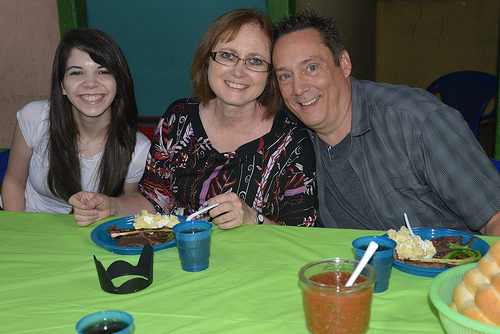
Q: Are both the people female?
A: No, they are both male and female.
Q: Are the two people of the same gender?
A: No, they are both male and female.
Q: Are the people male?
A: No, they are both male and female.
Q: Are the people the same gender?
A: No, they are both male and female.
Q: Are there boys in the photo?
A: No, there are no boys.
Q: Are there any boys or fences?
A: No, there are no boys or fences.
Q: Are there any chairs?
A: Yes, there is a chair.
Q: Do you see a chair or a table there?
A: Yes, there is a chair.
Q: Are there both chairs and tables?
A: Yes, there are both a chair and a table.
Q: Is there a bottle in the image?
A: No, there are no bottles.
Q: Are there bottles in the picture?
A: No, there are no bottles.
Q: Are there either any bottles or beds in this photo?
A: No, there are no bottles or beds.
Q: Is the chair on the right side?
A: Yes, the chair is on the right of the image.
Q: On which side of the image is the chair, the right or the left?
A: The chair is on the right of the image.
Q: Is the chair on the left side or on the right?
A: The chair is on the right of the image.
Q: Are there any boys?
A: No, there are no boys.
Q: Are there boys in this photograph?
A: No, there are no boys.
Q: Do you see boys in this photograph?
A: No, there are no boys.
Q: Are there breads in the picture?
A: Yes, there is a bread.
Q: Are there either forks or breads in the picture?
A: Yes, there is a bread.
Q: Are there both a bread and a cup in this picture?
A: Yes, there are both a bread and a cup.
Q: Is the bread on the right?
A: Yes, the bread is on the right of the image.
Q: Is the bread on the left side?
A: No, the bread is on the right of the image.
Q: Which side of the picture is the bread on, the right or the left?
A: The bread is on the right of the image.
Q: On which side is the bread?
A: The bread is on the right of the image.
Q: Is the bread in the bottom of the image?
A: Yes, the bread is in the bottom of the image.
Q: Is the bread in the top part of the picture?
A: No, the bread is in the bottom of the image.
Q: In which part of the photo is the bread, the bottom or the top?
A: The bread is in the bottom of the image.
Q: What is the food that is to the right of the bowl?
A: The food is a bread.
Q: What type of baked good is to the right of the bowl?
A: The food is a bread.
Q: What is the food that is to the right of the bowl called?
A: The food is a bread.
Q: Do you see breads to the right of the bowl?
A: Yes, there is a bread to the right of the bowl.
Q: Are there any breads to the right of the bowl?
A: Yes, there is a bread to the right of the bowl.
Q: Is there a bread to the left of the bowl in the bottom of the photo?
A: No, the bread is to the right of the bowl.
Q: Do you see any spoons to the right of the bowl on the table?
A: No, there is a bread to the right of the bowl.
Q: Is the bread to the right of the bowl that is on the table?
A: Yes, the bread is to the right of the bowl.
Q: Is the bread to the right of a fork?
A: No, the bread is to the right of the bowl.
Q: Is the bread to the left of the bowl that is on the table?
A: No, the bread is to the right of the bowl.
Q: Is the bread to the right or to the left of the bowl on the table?
A: The bread is to the right of the bowl.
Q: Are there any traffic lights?
A: No, there are no traffic lights.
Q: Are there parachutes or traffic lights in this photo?
A: No, there are no traffic lights or parachutes.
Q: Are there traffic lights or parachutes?
A: No, there are no traffic lights or parachutes.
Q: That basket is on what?
A: The basket is on the table.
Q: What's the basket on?
A: The basket is on the table.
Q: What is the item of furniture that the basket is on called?
A: The piece of furniture is a table.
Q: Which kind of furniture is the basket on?
A: The basket is on the table.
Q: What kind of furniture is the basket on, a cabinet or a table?
A: The basket is on a table.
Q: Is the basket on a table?
A: Yes, the basket is on a table.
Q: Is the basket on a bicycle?
A: No, the basket is on a table.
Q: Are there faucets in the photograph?
A: No, there are no faucets.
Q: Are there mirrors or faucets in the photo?
A: No, there are no faucets or mirrors.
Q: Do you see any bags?
A: No, there are no bags.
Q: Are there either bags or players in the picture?
A: No, there are no bags or players.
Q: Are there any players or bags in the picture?
A: No, there are no bags or players.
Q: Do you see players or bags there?
A: No, there are no bags or players.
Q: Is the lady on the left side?
A: Yes, the lady is on the left of the image.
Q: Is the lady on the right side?
A: No, the lady is on the left of the image.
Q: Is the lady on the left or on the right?
A: The lady is on the left of the image.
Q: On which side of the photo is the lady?
A: The lady is on the left of the image.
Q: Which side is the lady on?
A: The lady is on the left of the image.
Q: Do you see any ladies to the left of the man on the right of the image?
A: Yes, there is a lady to the left of the man.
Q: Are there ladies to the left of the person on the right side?
A: Yes, there is a lady to the left of the man.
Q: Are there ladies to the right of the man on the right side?
A: No, the lady is to the left of the man.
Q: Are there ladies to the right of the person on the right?
A: No, the lady is to the left of the man.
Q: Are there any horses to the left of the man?
A: No, there is a lady to the left of the man.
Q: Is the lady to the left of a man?
A: Yes, the lady is to the left of a man.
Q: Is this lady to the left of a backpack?
A: No, the lady is to the left of a man.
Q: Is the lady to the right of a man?
A: No, the lady is to the left of a man.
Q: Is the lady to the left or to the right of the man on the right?
A: The lady is to the left of the man.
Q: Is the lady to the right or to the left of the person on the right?
A: The lady is to the left of the man.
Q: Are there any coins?
A: No, there are no coins.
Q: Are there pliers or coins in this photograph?
A: No, there are no coins or pliers.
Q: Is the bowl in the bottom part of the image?
A: Yes, the bowl is in the bottom of the image.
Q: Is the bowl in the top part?
A: No, the bowl is in the bottom of the image.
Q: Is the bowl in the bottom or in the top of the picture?
A: The bowl is in the bottom of the image.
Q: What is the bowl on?
A: The bowl is on the table.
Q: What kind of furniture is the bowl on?
A: The bowl is on the table.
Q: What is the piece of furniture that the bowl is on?
A: The piece of furniture is a table.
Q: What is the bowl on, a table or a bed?
A: The bowl is on a table.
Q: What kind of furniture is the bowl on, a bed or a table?
A: The bowl is on a table.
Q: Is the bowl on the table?
A: Yes, the bowl is on the table.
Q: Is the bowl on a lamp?
A: No, the bowl is on the table.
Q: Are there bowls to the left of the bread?
A: Yes, there is a bowl to the left of the bread.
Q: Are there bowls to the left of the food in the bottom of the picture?
A: Yes, there is a bowl to the left of the bread.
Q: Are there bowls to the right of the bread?
A: No, the bowl is to the left of the bread.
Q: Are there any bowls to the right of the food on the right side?
A: No, the bowl is to the left of the bread.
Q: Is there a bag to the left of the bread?
A: No, there is a bowl to the left of the bread.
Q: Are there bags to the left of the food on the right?
A: No, there is a bowl to the left of the bread.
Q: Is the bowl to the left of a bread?
A: Yes, the bowl is to the left of a bread.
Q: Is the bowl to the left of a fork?
A: No, the bowl is to the left of a bread.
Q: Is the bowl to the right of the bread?
A: No, the bowl is to the left of the bread.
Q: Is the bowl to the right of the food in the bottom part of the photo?
A: No, the bowl is to the left of the bread.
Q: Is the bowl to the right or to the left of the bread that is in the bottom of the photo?
A: The bowl is to the left of the bread.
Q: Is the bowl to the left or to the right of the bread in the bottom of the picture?
A: The bowl is to the left of the bread.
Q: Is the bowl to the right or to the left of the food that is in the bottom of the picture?
A: The bowl is to the left of the bread.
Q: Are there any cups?
A: Yes, there is a cup.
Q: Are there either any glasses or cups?
A: Yes, there is a cup.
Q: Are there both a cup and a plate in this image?
A: Yes, there are both a cup and a plate.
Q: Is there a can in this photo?
A: No, there are no cans.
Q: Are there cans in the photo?
A: No, there are no cans.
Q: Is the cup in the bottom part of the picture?
A: Yes, the cup is in the bottom of the image.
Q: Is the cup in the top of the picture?
A: No, the cup is in the bottom of the image.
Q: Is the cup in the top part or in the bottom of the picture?
A: The cup is in the bottom of the image.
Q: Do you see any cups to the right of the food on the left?
A: Yes, there is a cup to the right of the food.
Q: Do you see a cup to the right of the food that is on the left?
A: Yes, there is a cup to the right of the food.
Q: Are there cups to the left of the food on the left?
A: No, the cup is to the right of the food.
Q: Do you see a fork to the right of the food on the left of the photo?
A: No, there is a cup to the right of the food.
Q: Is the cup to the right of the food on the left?
A: Yes, the cup is to the right of the food.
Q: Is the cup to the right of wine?
A: No, the cup is to the right of the food.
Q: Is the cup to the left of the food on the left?
A: No, the cup is to the right of the food.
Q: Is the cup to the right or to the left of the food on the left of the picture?
A: The cup is to the right of the food.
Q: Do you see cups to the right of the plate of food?
A: Yes, there is a cup to the right of the plate.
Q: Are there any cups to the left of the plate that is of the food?
A: No, the cup is to the right of the plate.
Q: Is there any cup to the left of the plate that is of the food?
A: No, the cup is to the right of the plate.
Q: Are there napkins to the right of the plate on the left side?
A: No, there is a cup to the right of the plate.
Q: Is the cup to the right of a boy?
A: No, the cup is to the right of the plate.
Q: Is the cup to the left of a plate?
A: No, the cup is to the right of a plate.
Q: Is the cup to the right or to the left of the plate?
A: The cup is to the right of the plate.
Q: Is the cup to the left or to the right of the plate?
A: The cup is to the right of the plate.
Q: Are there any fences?
A: No, there are no fences.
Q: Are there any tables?
A: Yes, there is a table.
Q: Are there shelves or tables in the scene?
A: Yes, there is a table.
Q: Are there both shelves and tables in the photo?
A: No, there is a table but no shelves.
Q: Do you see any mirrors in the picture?
A: No, there are no mirrors.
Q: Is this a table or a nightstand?
A: This is a table.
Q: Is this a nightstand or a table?
A: This is a table.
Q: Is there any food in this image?
A: Yes, there is food.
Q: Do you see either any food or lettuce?
A: Yes, there is food.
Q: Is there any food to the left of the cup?
A: Yes, there is food to the left of the cup.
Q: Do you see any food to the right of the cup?
A: No, the food is to the left of the cup.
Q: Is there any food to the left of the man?
A: Yes, there is food to the left of the man.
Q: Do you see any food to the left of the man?
A: Yes, there is food to the left of the man.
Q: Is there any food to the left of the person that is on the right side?
A: Yes, there is food to the left of the man.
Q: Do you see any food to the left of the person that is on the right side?
A: Yes, there is food to the left of the man.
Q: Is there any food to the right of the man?
A: No, the food is to the left of the man.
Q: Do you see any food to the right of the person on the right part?
A: No, the food is to the left of the man.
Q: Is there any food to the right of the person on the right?
A: No, the food is to the left of the man.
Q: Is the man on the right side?
A: Yes, the man is on the right of the image.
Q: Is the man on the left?
A: No, the man is on the right of the image.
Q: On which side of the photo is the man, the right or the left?
A: The man is on the right of the image.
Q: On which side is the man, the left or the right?
A: The man is on the right of the image.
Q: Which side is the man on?
A: The man is on the right of the image.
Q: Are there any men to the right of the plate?
A: Yes, there is a man to the right of the plate.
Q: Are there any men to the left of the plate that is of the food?
A: No, the man is to the right of the plate.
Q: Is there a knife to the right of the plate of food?
A: No, there is a man to the right of the plate.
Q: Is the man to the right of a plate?
A: Yes, the man is to the right of a plate.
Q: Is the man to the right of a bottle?
A: No, the man is to the right of a plate.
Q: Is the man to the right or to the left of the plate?
A: The man is to the right of the plate.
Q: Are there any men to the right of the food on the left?
A: Yes, there is a man to the right of the food.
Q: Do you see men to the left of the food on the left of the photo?
A: No, the man is to the right of the food.